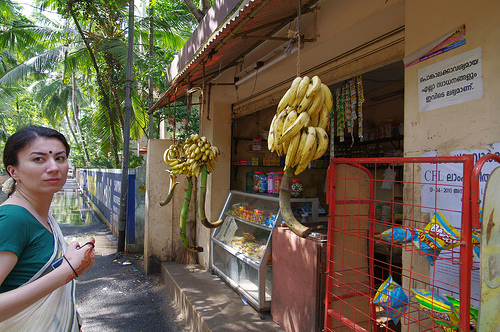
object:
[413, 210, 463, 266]
chips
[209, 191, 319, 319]
counter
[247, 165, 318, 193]
items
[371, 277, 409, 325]
chips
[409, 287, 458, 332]
chips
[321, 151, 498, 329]
red shelf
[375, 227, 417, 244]
chips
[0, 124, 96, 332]
woman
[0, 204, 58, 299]
shirt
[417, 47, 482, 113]
signs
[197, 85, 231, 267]
wall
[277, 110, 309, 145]
bananas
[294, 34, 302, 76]
string